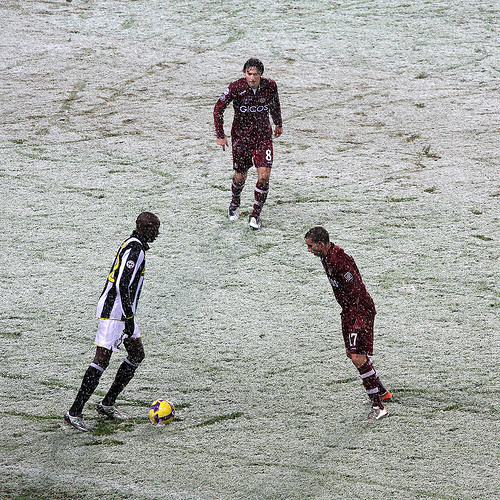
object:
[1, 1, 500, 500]
snow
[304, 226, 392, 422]
man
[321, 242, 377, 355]
uniform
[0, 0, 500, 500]
field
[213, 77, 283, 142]
shirt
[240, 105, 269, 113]
letters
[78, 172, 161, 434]
man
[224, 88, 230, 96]
logo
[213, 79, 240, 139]
sleeve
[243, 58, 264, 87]
head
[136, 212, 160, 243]
head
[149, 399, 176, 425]
ball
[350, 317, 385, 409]
legs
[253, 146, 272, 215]
legs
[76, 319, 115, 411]
legs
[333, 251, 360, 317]
arm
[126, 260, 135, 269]
print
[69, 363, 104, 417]
knee socks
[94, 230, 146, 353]
uniform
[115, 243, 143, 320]
arm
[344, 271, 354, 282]
logo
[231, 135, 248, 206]
leg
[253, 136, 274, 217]
leg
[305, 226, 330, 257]
head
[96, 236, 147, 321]
jersey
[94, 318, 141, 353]
shorts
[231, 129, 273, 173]
shorts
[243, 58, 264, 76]
hair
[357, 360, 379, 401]
sock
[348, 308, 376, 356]
sock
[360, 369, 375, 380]
stripe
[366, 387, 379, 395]
stripe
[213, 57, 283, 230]
man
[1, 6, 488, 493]
rain